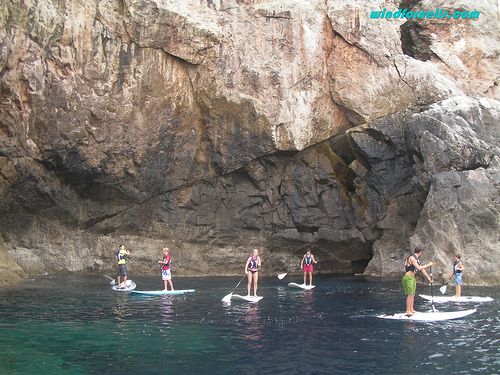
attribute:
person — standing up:
[453, 254, 464, 295]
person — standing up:
[399, 248, 424, 314]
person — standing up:
[244, 248, 263, 293]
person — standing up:
[113, 246, 130, 285]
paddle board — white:
[419, 291, 494, 308]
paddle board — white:
[374, 310, 477, 323]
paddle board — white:
[285, 282, 316, 291]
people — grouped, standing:
[107, 232, 462, 317]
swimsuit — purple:
[251, 256, 263, 281]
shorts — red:
[294, 259, 312, 276]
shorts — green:
[393, 271, 428, 305]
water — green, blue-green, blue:
[23, 280, 484, 368]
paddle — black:
[423, 270, 437, 311]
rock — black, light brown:
[259, 193, 429, 281]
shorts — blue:
[453, 271, 466, 290]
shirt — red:
[161, 255, 171, 276]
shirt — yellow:
[111, 244, 132, 270]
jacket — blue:
[446, 254, 458, 272]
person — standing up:
[158, 243, 176, 290]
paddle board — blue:
[131, 287, 197, 297]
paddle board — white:
[231, 293, 265, 303]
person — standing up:
[300, 247, 317, 285]